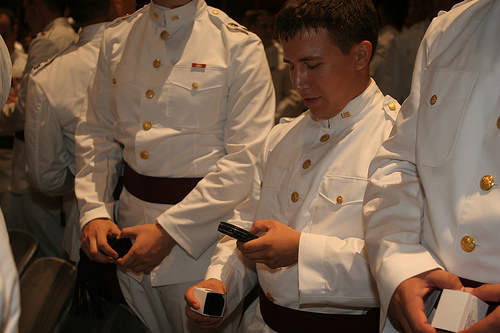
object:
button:
[458, 234, 478, 253]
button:
[319, 133, 331, 142]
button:
[301, 157, 312, 170]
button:
[290, 190, 299, 203]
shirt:
[202, 78, 403, 333]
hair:
[271, 0, 383, 67]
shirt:
[360, 0, 500, 333]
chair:
[6, 227, 40, 279]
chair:
[17, 252, 80, 333]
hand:
[112, 220, 173, 277]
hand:
[78, 215, 124, 265]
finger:
[116, 244, 141, 269]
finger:
[234, 235, 268, 254]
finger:
[426, 267, 468, 294]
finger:
[397, 278, 437, 332]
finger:
[94, 226, 119, 260]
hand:
[233, 217, 302, 272]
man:
[20, 0, 140, 304]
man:
[72, 0, 280, 333]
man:
[360, 0, 500, 330]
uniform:
[21, 21, 125, 264]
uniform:
[71, 0, 278, 333]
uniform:
[202, 75, 400, 333]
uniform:
[359, 1, 500, 331]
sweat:
[292, 28, 330, 90]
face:
[279, 24, 358, 121]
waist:
[139, 198, 188, 259]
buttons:
[458, 234, 479, 253]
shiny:
[454, 232, 480, 255]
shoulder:
[192, 28, 267, 54]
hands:
[383, 266, 469, 333]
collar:
[307, 77, 385, 130]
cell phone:
[215, 221, 261, 243]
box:
[427, 286, 492, 333]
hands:
[452, 280, 499, 333]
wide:
[122, 161, 204, 205]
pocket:
[163, 60, 229, 133]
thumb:
[247, 216, 283, 235]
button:
[264, 291, 274, 304]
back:
[18, 255, 81, 333]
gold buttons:
[141, 120, 155, 132]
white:
[267, 206, 294, 219]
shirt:
[70, 0, 279, 264]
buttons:
[139, 149, 151, 161]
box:
[185, 283, 228, 320]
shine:
[303, 36, 323, 55]